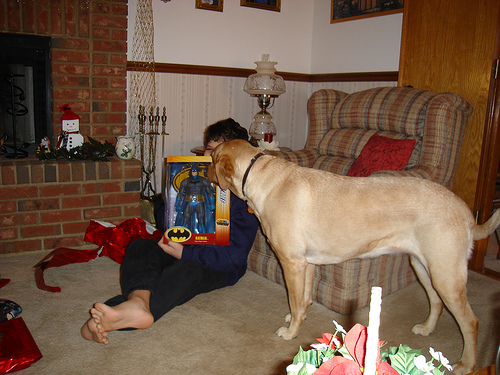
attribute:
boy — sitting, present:
[75, 116, 260, 346]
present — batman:
[158, 149, 233, 250]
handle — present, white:
[363, 283, 392, 374]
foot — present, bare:
[88, 298, 157, 332]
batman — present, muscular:
[161, 152, 235, 248]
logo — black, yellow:
[163, 224, 195, 244]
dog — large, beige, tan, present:
[202, 136, 497, 374]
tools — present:
[134, 97, 173, 207]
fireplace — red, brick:
[2, 0, 143, 260]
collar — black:
[240, 149, 269, 200]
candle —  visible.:
[257, 131, 282, 152]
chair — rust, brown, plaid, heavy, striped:
[247, 82, 477, 317]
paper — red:
[27, 212, 169, 300]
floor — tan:
[0, 250, 494, 374]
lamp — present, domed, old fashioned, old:
[243, 50, 286, 154]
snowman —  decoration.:
[53, 101, 88, 158]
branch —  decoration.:
[40, 136, 116, 162]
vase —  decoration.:
[114, 130, 138, 160]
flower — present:
[290, 320, 395, 374]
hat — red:
[58, 101, 82, 122]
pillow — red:
[341, 129, 421, 180]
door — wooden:
[399, 0, 499, 272]